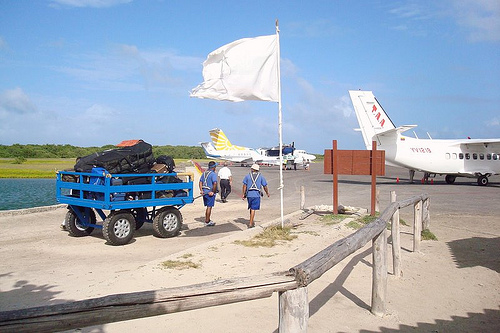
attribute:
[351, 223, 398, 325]
fence post — wooden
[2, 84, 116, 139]
clouds — white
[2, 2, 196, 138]
sky — blue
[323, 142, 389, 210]
sign — wooden, brown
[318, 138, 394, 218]
sign — brown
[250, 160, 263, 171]
hat — white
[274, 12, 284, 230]
pole — metal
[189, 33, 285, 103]
flag — white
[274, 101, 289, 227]
pole — metal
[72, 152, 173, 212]
wagon — medium blue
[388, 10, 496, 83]
clouds — white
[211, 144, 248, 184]
shirt — white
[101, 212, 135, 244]
tire — black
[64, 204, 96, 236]
tire — black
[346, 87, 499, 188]
airplane — white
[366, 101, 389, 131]
words — red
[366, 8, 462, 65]
sky — blue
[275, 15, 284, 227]
pole — metal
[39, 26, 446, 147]
sky — bright blue 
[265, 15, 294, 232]
pole — metal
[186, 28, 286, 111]
flag — white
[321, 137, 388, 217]
sign — brown, wooden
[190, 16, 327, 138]
flag — white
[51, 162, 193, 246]
cart — blue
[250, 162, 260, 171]
hat — white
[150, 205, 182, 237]
tire — black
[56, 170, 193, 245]
trailer — blue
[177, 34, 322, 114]
flag — white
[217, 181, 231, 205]
pants — black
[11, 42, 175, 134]
clouds — white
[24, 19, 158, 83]
sky — blue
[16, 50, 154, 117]
clouds — white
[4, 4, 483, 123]
sky — blue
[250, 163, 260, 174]
hat — white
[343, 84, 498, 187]
plane — white, red